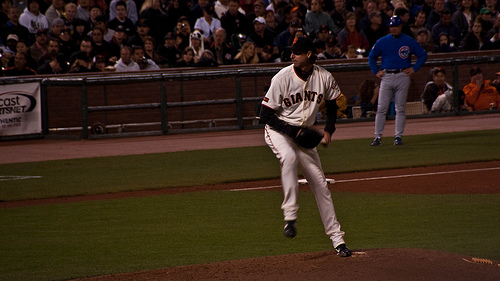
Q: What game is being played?
A: Baseball.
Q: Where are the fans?
A: Fan stands.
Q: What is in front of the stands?
A: Wall.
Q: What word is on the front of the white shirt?
A: Giants.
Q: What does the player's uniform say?
A: Giants.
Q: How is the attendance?
A: Good.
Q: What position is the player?
A: Pitcher.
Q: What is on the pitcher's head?
A: Baseball cap.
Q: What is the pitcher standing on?
A: Dirt.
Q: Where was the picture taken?
A: At a baseball park.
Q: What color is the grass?
A: Green.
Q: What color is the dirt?
A: Brown.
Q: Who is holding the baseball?
A: The man on the mound.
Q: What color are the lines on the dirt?
A: White.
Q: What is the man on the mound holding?
A: A ball.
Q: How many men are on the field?
A: Two.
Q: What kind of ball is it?
A: A baseball.